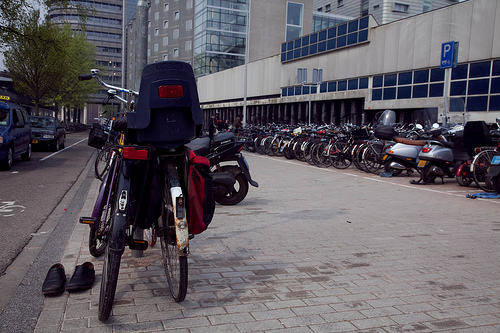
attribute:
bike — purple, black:
[66, 60, 155, 320]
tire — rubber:
[98, 251, 118, 319]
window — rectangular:
[448, 62, 468, 79]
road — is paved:
[20, 119, 100, 331]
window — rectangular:
[368, 70, 386, 88]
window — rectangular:
[414, 68, 429, 78]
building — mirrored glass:
[177, 9, 246, 80]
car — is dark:
[34, 105, 63, 150]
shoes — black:
[39, 255, 98, 300]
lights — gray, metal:
[272, 50, 357, 119]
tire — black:
[152, 221, 193, 306]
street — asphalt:
[0, 126, 105, 331]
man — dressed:
[188, 80, 268, 175]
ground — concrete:
[298, 175, 423, 285]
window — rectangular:
[392, 88, 419, 100]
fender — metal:
[94, 186, 126, 239]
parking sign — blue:
[440, 39, 457, 72]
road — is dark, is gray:
[2, 113, 105, 331]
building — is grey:
[197, 5, 488, 147]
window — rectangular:
[383, 72, 398, 85]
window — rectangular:
[374, 55, 444, 107]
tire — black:
[89, 184, 144, 319]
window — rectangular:
[394, 67, 416, 86]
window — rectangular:
[406, 71, 486, 106]